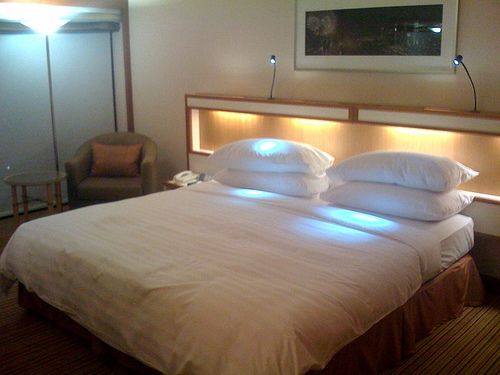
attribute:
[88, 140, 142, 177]
pillow — brown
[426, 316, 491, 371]
rug — striped, multi colored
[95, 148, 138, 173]
pillow — brown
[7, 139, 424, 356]
bed — white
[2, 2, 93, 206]
tall lamp — skinny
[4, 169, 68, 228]
table — small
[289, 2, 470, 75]
picture — dark colored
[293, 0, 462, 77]
picture — rectangular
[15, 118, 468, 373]
bed — white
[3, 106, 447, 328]
bed — brown, white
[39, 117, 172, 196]
chair — brown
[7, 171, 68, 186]
brown table — small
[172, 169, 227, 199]
telephone — white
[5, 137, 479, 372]
bed — large, clean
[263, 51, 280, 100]
light fixture — long, thin, black 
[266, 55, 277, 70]
light — blue colored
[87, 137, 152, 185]
pillow — large, light brown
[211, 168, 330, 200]
pillow — white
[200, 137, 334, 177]
pillow — white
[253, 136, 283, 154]
lighting — blue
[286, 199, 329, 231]
sheet — white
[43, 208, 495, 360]
bed — white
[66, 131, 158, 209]
chair — small, greenish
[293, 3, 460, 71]
frame — large, white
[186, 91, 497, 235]
paneling — wooden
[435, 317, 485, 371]
stripes — gray, brown, black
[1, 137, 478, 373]
bedding — white